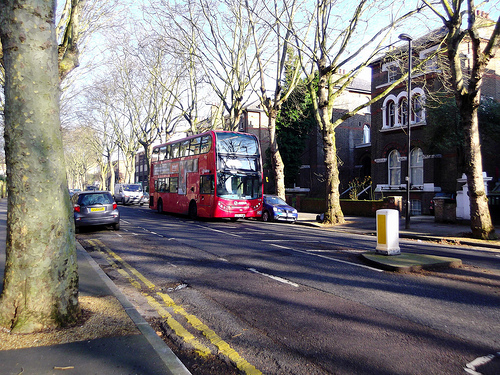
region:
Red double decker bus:
[151, 130, 265, 220]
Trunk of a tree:
[1, 0, 79, 336]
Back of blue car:
[72, 192, 120, 227]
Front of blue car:
[262, 194, 299, 224]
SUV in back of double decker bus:
[112, 182, 145, 199]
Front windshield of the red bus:
[213, 159, 263, 197]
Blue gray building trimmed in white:
[367, 43, 497, 227]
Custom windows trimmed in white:
[381, 87, 427, 133]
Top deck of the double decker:
[146, 129, 262, 157]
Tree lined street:
[57, 0, 498, 240]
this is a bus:
[147, 140, 250, 225]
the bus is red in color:
[179, 161, 196, 201]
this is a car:
[261, 195, 293, 217]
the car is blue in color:
[276, 199, 290, 219]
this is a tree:
[291, 38, 352, 167]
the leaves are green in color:
[432, 115, 449, 131]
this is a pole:
[401, 34, 418, 234]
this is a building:
[367, 112, 401, 167]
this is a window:
[381, 99, 395, 124]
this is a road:
[229, 238, 301, 318]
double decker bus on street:
[137, 128, 269, 215]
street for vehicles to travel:
[121, 237, 476, 342]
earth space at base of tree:
[5, 283, 129, 343]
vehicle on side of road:
[61, 172, 123, 229]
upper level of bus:
[148, 127, 258, 155]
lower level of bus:
[149, 174, 261, 196]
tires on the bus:
[143, 197, 205, 219]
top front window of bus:
[221, 133, 260, 156]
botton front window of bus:
[216, 173, 256, 198]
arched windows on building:
[380, 143, 422, 180]